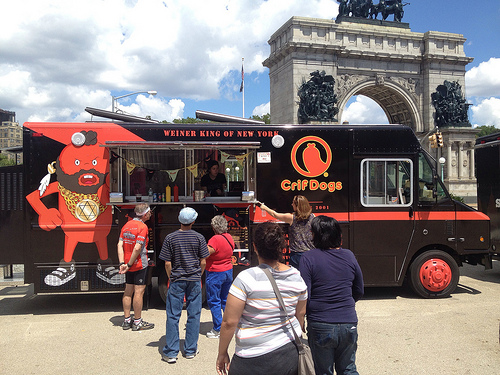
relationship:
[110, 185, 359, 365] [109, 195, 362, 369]
people waiting in line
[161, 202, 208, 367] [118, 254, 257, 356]
man wearing blue jeans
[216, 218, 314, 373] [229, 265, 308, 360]
woman wearing shirt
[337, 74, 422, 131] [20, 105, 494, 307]
archway behind truck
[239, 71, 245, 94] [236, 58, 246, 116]
flag flying from pole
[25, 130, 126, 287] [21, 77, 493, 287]
caricature on side of truck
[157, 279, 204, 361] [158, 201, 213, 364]
blue jeans on person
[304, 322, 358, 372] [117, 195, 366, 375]
jeans on people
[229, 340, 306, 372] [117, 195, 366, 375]
gray pants on people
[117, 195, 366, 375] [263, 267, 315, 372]
people carrying bag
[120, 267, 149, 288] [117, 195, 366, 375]
shorts on people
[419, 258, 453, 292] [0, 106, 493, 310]
hub caps on food truck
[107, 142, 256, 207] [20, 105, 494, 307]
window on truck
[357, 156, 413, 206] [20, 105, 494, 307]
window on truck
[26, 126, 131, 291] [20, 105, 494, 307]
caricature on truck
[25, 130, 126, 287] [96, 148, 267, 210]
caricature beside windows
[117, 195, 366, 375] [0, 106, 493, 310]
people waiting at food truck